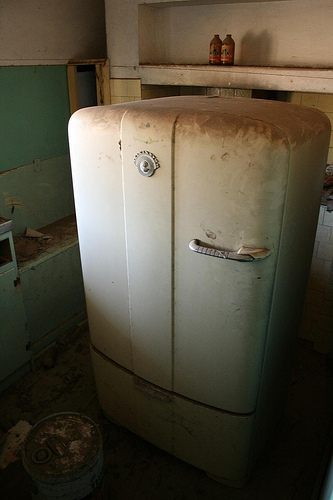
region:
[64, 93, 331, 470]
antique white fridge with dust on top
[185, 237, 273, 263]
long silver handle on fridge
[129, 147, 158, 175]
silver logo on white fridge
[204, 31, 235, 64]
two old bottles sitting on white shelf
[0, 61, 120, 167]
dirty green wall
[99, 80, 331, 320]
yellow ceramic tile on wall behind fridge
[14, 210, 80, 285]
filthy built in seat against wall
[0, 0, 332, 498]
Abandoned and neglected kitchen.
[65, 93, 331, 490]
Old white refrigerator.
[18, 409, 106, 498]
Small metal canister on dirty floor.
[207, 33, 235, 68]
Two bottles on a shelf.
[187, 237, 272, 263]
Metal refrigerator door handle.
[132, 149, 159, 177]
Refrigerator door product logo.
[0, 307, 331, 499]
Dirty concrete floor.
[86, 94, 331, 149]
Thick dust layer on old refrigerator.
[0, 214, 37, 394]
Blue cabinet with metal frame counter top.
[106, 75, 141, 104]
Yellow wall tile.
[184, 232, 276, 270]
Handle color silver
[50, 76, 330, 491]
the refrigerator is dirty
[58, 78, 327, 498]
the refrigerator is color white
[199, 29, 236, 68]
two bottles color brown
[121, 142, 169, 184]
silver logo over white surface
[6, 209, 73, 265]
dirty over a counter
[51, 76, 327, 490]
top of refrigerator is dirty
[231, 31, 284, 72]
shadows of bottles cast on white wall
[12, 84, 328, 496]
refrigerator on a dirty floor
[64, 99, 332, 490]
old, white, antique refrigerator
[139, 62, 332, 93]
white shelf above the refrigerator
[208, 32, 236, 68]
old brown bottles on the shelf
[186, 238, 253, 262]
chrome, silver handle on refrigerator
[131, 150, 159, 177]
chrome, silver logo on refrigerator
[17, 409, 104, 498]
paint bucket with dirt on top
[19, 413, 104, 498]
paint bucket in front of refrigerator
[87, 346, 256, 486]
freezer drawer on the refrigerator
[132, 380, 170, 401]
handle on the freezer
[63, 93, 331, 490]
refrigerator is old and white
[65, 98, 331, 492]
a dirty old ice chest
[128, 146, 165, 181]
the logo of an old refrigeration company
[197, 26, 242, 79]
two old bottles on a shelf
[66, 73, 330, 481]
a rusty old refrigerator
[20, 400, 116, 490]
a very rusty oil can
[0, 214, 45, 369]
a small metal oven door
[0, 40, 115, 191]
an exposed section of a wall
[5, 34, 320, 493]
a dingy old ripped up kitchen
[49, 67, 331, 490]
this is an old fidge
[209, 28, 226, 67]
this is a bottle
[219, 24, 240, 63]
this is a bottle